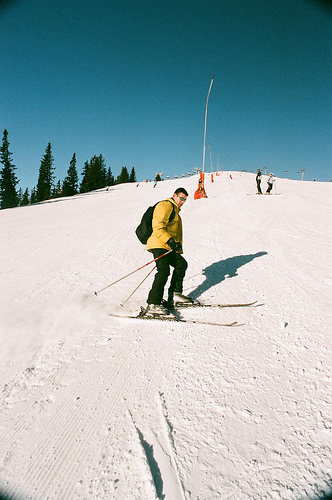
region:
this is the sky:
[79, 29, 262, 76]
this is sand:
[86, 370, 219, 470]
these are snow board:
[111, 292, 261, 350]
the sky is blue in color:
[219, 10, 285, 75]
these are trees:
[44, 144, 132, 190]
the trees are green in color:
[42, 142, 94, 196]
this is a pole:
[190, 68, 217, 200]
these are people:
[125, 162, 300, 204]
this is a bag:
[128, 201, 160, 248]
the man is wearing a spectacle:
[174, 193, 189, 204]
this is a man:
[133, 184, 190, 305]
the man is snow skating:
[129, 189, 206, 322]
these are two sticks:
[93, 257, 146, 306]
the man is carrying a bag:
[135, 203, 157, 238]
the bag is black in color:
[135, 207, 151, 240]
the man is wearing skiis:
[149, 291, 191, 322]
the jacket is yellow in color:
[154, 210, 178, 242]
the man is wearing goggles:
[180, 195, 186, 199]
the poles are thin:
[104, 256, 149, 300]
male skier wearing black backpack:
[135, 202, 157, 244]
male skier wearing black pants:
[147, 254, 190, 297]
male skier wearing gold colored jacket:
[142, 197, 187, 253]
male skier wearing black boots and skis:
[142, 287, 259, 331]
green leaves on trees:
[0, 126, 25, 211]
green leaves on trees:
[84, 146, 116, 195]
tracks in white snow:
[9, 340, 181, 496]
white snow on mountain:
[180, 332, 317, 491]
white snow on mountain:
[225, 202, 318, 294]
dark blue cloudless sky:
[9, 14, 322, 127]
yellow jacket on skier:
[145, 195, 184, 255]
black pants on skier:
[147, 246, 187, 302]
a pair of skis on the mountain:
[107, 293, 259, 326]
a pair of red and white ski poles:
[87, 248, 174, 312]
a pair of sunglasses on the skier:
[176, 192, 188, 200]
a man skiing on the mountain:
[133, 188, 191, 314]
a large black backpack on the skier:
[135, 202, 154, 246]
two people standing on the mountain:
[245, 168, 279, 197]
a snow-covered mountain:
[1, 171, 331, 499]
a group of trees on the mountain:
[0, 128, 160, 209]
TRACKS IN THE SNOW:
[107, 392, 188, 495]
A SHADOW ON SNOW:
[174, 240, 267, 297]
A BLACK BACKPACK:
[121, 193, 172, 236]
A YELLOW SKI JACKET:
[137, 194, 181, 251]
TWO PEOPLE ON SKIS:
[238, 158, 281, 198]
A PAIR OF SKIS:
[100, 292, 252, 320]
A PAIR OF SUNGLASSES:
[168, 185, 182, 195]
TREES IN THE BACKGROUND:
[0, 123, 142, 206]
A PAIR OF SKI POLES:
[84, 241, 174, 304]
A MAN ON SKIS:
[86, 182, 269, 335]